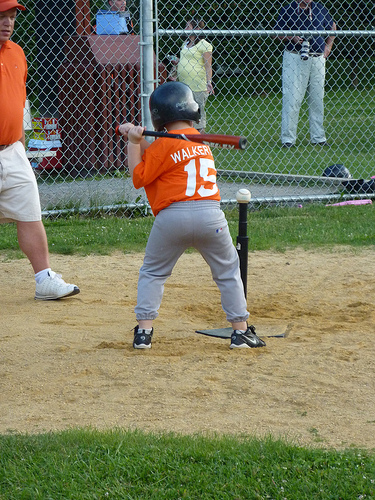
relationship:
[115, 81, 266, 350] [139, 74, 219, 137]
batter wearing a helmet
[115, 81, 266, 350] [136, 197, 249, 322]
batter wearing pants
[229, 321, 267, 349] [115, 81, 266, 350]
shoe on batter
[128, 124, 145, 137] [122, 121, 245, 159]
hand on bat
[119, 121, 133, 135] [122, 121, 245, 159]
hand on bat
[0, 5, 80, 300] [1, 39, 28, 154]
man wearing shirt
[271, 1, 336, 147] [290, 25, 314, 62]
blue shirt with camera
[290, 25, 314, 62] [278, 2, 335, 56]
camera in a blue shirt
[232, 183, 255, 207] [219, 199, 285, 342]
baseball on tee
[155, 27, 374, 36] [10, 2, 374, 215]
metal pole on chainlink fence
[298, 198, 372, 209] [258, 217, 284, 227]
bat lying on grass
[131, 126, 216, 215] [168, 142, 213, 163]
jersey says walker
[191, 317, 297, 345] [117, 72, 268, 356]
home plate by batter